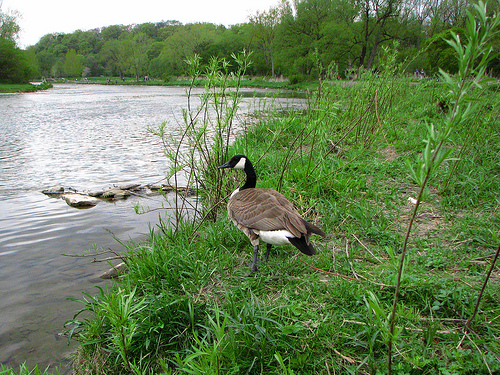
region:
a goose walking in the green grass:
[196, 137, 326, 277]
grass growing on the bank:
[77, 69, 345, 373]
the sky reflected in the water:
[12, 65, 260, 373]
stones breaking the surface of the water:
[42, 173, 200, 214]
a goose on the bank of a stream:
[170, 98, 334, 280]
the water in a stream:
[1, 71, 306, 373]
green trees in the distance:
[4, 6, 498, 81]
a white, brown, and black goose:
[208, 151, 323, 273]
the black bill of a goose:
[215, 163, 236, 171]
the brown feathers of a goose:
[230, 189, 315, 237]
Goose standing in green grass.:
[211, 152, 326, 287]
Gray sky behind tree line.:
[1, 0, 498, 50]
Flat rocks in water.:
[41, 176, 208, 208]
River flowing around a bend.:
[0, 82, 335, 364]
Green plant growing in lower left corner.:
[387, 0, 497, 374]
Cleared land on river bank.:
[40, 57, 444, 86]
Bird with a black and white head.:
[216, 142, 333, 283]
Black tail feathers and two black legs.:
[233, 235, 315, 278]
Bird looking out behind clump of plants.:
[166, 46, 251, 223]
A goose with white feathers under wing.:
[214, 150, 318, 285]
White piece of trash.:
[410, 190, 438, 219]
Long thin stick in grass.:
[381, 156, 441, 361]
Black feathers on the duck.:
[288, 233, 311, 256]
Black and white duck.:
[215, 142, 264, 185]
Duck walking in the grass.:
[204, 144, 316, 278]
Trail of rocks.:
[59, 180, 90, 208]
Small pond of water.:
[30, 226, 138, 349]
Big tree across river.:
[324, 15, 424, 70]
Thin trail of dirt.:
[393, 124, 445, 255]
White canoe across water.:
[26, 65, 50, 83]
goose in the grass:
[176, 120, 314, 288]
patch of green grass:
[263, 328, 295, 363]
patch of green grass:
[324, 308, 355, 352]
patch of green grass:
[151, 293, 163, 325]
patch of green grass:
[313, 285, 336, 311]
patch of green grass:
[385, 283, 416, 315]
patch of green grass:
[241, 290, 271, 321]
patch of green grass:
[310, 339, 353, 368]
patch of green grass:
[208, 346, 235, 371]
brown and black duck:
[219, 152, 317, 277]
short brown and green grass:
[135, 296, 196, 342]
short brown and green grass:
[241, 293, 277, 347]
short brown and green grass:
[301, 303, 363, 363]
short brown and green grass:
[375, 160, 415, 205]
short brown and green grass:
[275, 155, 327, 191]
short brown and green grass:
[325, 101, 385, 146]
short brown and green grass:
[446, 166, 496, 197]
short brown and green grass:
[321, 121, 376, 171]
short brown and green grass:
[359, 91, 421, 124]